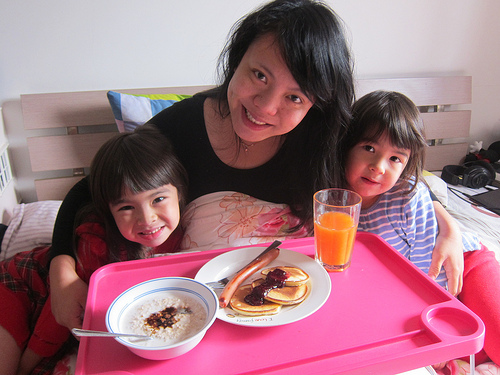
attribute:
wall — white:
[0, 2, 497, 174]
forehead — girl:
[362, 120, 412, 152]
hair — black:
[222, 3, 364, 132]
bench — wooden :
[2, 55, 496, 172]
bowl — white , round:
[105, 274, 219, 361]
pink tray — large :
[71, 225, 491, 374]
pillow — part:
[75, 89, 188, 140]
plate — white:
[195, 246, 335, 333]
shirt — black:
[170, 132, 199, 162]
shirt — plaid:
[355, 171, 454, 288]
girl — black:
[90, 125, 190, 258]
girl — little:
[338, 85, 498, 372]